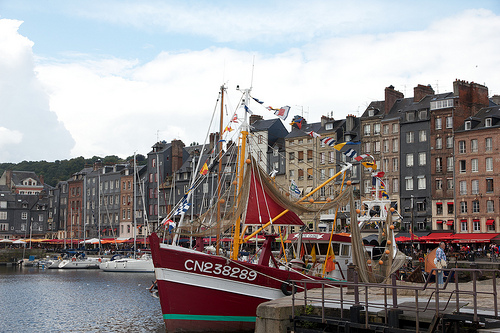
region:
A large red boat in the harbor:
[136, 120, 375, 329]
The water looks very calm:
[28, 293, 129, 320]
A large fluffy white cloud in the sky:
[0, 19, 80, 160]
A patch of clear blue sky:
[45, 31, 130, 54]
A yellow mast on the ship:
[223, 127, 259, 267]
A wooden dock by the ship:
[285, 276, 492, 321]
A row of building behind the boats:
[41, 149, 488, 226]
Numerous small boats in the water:
[24, 248, 151, 273]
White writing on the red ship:
[180, 254, 258, 285]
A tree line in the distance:
[0, 151, 132, 191]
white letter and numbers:
[170, 244, 262, 297]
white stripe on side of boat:
[149, 259, 274, 314]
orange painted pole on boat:
[227, 117, 272, 265]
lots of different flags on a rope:
[251, 84, 389, 186]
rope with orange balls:
[374, 192, 409, 281]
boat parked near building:
[13, 224, 150, 278]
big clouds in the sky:
[21, 58, 146, 137]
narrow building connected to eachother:
[397, 101, 494, 203]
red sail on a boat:
[237, 147, 315, 233]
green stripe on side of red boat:
[159, 303, 257, 331]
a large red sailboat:
[144, 86, 374, 330]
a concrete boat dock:
[252, 278, 499, 328]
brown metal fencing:
[292, 275, 499, 325]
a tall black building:
[399, 106, 430, 232]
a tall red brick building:
[432, 80, 487, 234]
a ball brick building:
[359, 83, 401, 225]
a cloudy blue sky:
[0, 0, 499, 164]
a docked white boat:
[95, 252, 155, 273]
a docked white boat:
[54, 255, 99, 268]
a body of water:
[3, 265, 255, 331]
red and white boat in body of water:
[140, 81, 356, 329]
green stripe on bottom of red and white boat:
[159, 307, 255, 327]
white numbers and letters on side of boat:
[171, 250, 267, 288]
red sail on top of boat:
[239, 148, 312, 236]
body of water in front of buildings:
[3, 266, 163, 329]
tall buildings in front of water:
[3, 76, 498, 261]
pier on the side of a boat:
[251, 260, 499, 330]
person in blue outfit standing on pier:
[423, 236, 453, 292]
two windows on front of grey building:
[401, 126, 430, 145]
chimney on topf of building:
[383, 80, 405, 104]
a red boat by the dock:
[138, 48, 358, 325]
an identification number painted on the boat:
[176, 255, 257, 282]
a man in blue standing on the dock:
[427, 240, 454, 287]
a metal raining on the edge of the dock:
[286, 268, 498, 326]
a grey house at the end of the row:
[1, 168, 60, 243]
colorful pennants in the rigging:
[150, 82, 382, 234]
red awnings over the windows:
[427, 198, 498, 229]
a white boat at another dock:
[97, 148, 162, 276]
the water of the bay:
[1, 264, 163, 329]